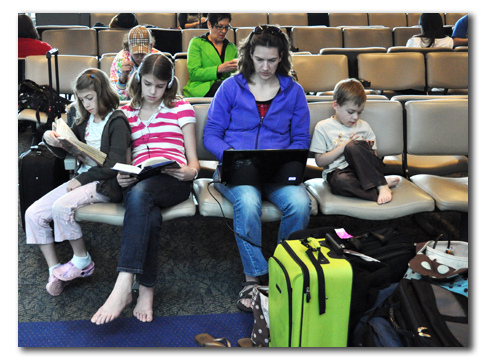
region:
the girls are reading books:
[57, 45, 202, 228]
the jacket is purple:
[196, 56, 327, 191]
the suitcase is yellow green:
[249, 241, 366, 358]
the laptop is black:
[214, 132, 322, 223]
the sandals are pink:
[33, 251, 106, 292]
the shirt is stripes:
[111, 96, 236, 216]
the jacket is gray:
[56, 108, 126, 216]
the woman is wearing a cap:
[107, 25, 173, 86]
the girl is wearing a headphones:
[118, 51, 180, 121]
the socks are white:
[46, 254, 108, 274]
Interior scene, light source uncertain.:
[19, 12, 483, 356]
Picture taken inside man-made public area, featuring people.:
[21, 17, 477, 350]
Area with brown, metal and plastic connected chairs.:
[26, 19, 443, 342]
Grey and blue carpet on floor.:
[21, 266, 75, 343]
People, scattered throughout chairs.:
[18, 4, 482, 328]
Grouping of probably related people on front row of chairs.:
[30, 33, 468, 322]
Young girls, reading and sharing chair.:
[27, 50, 187, 346]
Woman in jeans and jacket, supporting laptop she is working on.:
[203, 18, 306, 312]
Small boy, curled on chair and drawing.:
[313, 65, 400, 211]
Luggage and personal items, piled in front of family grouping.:
[190, 223, 483, 350]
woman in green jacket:
[183, 8, 257, 103]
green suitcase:
[254, 228, 360, 344]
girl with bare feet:
[84, 246, 175, 331]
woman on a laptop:
[211, 17, 328, 229]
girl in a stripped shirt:
[111, 46, 203, 335]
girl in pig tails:
[123, 48, 193, 117]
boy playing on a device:
[302, 66, 398, 203]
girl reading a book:
[19, 63, 118, 288]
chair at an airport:
[385, 81, 474, 244]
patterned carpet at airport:
[160, 246, 241, 322]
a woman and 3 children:
[26, 23, 401, 329]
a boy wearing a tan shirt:
[309, 74, 402, 205]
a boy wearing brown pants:
[309, 76, 400, 209]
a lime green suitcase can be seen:
[264, 230, 354, 347]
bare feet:
[88, 268, 160, 328]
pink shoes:
[44, 254, 96, 297]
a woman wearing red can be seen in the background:
[18, 12, 55, 53]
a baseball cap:
[123, 25, 152, 55]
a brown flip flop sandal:
[190, 327, 235, 347]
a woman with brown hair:
[232, 18, 293, 79]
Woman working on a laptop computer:
[203, 24, 316, 210]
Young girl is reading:
[109, 49, 188, 321]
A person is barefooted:
[89, 245, 182, 333]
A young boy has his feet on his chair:
[310, 81, 406, 212]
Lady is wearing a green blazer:
[178, 9, 237, 90]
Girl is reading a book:
[35, 63, 111, 172]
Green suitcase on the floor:
[234, 233, 392, 351]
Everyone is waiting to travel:
[32, 15, 427, 336]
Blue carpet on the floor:
[11, 310, 268, 348]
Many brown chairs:
[288, 13, 475, 94]